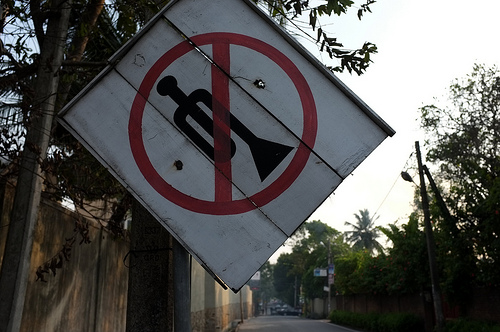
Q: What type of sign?
A: No music.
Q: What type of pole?
A: Electric.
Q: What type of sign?
A: No music.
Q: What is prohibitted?
A: Trumpets.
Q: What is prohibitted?
A: Trumpets.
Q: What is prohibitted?
A: Trumpets.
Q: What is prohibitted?
A: Trumpets.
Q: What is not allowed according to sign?
A: Trumpet.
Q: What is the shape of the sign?
A: Square.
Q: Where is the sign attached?
A: Pole on sidewalk.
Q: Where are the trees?
A: Along walkway.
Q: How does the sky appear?
A: Hazy.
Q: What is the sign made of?
A: Three panels.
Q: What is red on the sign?
A: Circle.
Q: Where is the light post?
A: On sidewalk.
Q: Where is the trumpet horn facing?
A: Downwards.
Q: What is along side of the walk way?
A: Wood fence.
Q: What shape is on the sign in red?
A: Circle.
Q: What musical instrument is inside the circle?
A: Trumpet.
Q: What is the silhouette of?
A: A trumpet.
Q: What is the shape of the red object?
A: Circle.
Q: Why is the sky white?
A: Clouds.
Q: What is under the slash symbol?
A: Trumpet.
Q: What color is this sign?
A: White.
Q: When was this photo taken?
A: Outside, during the daytime.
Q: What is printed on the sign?
A: An anti-trumpet/music image.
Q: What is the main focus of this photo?
A: A sign.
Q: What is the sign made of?
A: Wood.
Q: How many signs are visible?
A: One.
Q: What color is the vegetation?
A: Green.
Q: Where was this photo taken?
A: On an empty road.